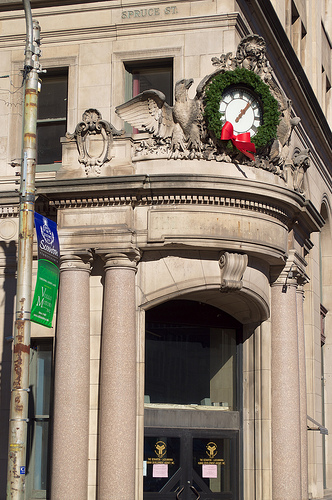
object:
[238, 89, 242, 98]
roman numeral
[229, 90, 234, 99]
roman numeral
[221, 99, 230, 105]
roman numeral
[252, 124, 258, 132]
roman numeral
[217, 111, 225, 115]
roman numeral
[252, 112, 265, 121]
number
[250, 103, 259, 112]
number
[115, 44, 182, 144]
window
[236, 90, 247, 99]
roman numeral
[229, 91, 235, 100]
roman numeral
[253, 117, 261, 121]
roman numeral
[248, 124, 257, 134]
roman numeral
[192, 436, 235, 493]
window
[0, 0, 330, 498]
building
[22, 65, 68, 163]
window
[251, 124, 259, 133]
number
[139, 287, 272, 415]
window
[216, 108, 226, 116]
number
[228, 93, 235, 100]
number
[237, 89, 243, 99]
number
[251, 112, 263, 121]
roman numeral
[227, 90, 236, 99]
roman numeral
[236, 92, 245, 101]
number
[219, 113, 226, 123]
numeral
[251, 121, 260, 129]
numeral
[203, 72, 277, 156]
clock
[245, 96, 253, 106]
roman numeral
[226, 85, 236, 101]
roman numeral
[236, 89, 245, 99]
roman numeral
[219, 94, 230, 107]
number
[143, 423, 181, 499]
window